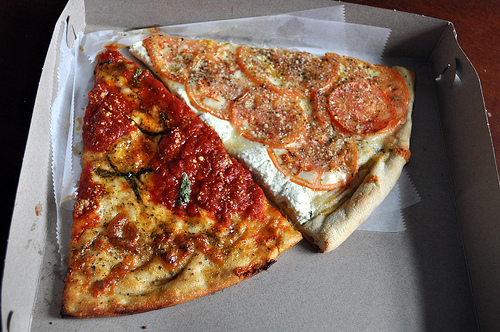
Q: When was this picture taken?
A: Daytime.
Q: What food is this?
A: Pizza.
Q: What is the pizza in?
A: Cardboard box.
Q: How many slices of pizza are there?
A: 2.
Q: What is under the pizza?
A: Tissue paper.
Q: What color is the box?
A: White.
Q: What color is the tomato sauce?
A: Red.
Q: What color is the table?
A: Brown.